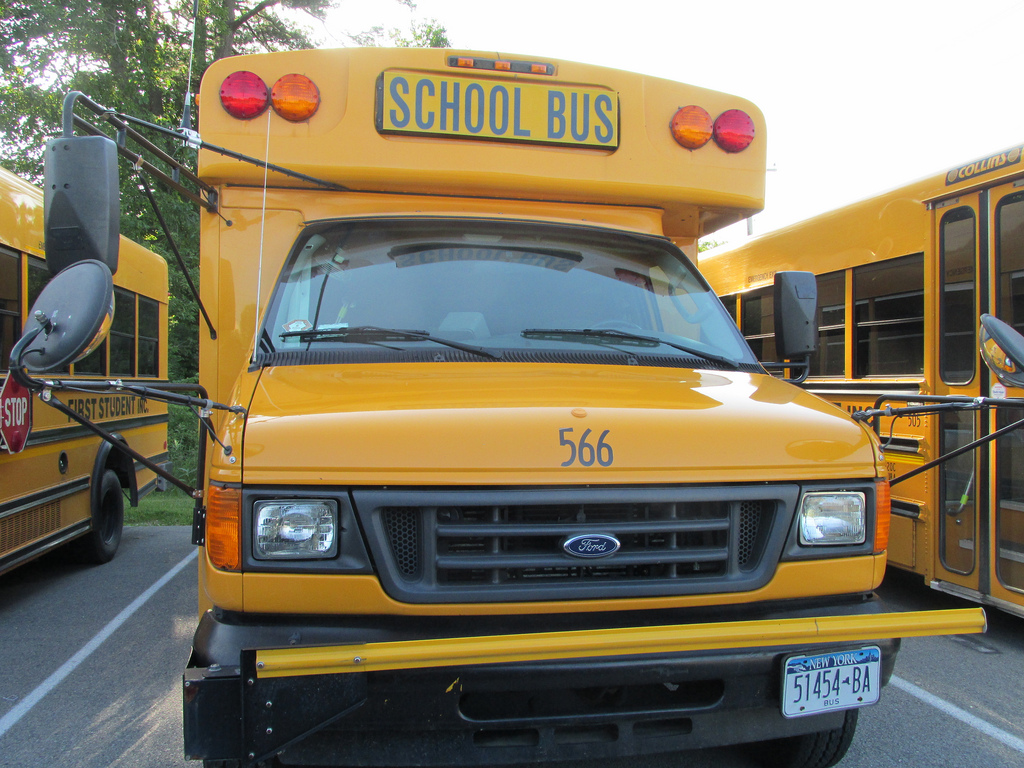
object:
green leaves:
[27, 5, 148, 92]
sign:
[381, 70, 619, 148]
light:
[714, 109, 757, 152]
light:
[271, 73, 320, 121]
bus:
[6, 48, 987, 768]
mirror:
[44, 135, 120, 277]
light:
[670, 104, 716, 148]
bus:
[696, 143, 1022, 618]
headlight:
[252, 499, 339, 560]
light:
[205, 484, 241, 569]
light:
[874, 481, 891, 552]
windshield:
[255, 219, 758, 364]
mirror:
[774, 271, 820, 360]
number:
[559, 427, 613, 466]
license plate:
[781, 646, 880, 720]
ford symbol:
[562, 533, 620, 557]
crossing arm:
[254, 606, 990, 680]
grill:
[350, 484, 801, 605]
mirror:
[24, 259, 117, 372]